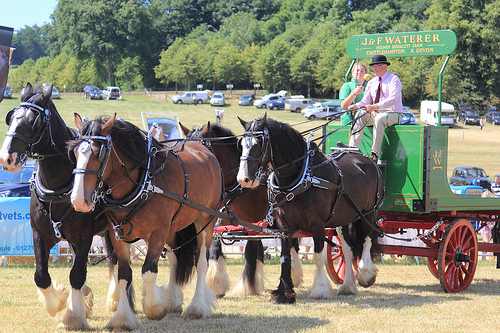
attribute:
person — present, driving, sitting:
[337, 56, 401, 162]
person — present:
[339, 62, 369, 126]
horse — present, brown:
[237, 114, 383, 303]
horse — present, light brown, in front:
[69, 112, 223, 325]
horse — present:
[1, 82, 94, 333]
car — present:
[84, 84, 102, 99]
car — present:
[103, 87, 122, 101]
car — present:
[173, 90, 208, 104]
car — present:
[210, 92, 226, 106]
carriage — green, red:
[325, 32, 498, 294]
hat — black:
[368, 54, 390, 67]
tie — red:
[374, 76, 382, 103]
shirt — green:
[339, 78, 370, 125]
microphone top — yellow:
[364, 74, 371, 81]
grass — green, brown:
[76, 102, 144, 111]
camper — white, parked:
[421, 100, 454, 128]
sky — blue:
[0, 2, 48, 22]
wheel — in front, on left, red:
[436, 218, 478, 293]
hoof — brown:
[275, 290, 296, 302]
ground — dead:
[0, 270, 499, 332]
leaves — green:
[196, 37, 338, 79]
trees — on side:
[27, 0, 497, 91]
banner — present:
[1, 196, 61, 255]